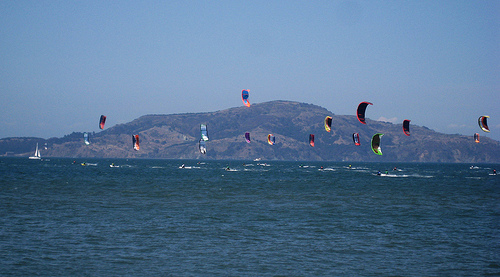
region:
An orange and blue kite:
[126, 128, 156, 170]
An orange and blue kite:
[232, 84, 255, 106]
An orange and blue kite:
[92, 110, 113, 129]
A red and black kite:
[354, 93, 379, 125]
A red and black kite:
[395, 114, 416, 139]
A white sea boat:
[20, 137, 52, 162]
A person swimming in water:
[373, 166, 386, 178]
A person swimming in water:
[222, 164, 239, 174]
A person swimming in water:
[388, 162, 410, 182]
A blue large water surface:
[163, 214, 372, 270]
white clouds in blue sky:
[0, 4, 57, 63]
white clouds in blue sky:
[47, 21, 92, 62]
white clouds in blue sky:
[126, 13, 157, 53]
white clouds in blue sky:
[186, 27, 228, 64]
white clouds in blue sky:
[274, 26, 309, 67]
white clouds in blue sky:
[354, 17, 407, 84]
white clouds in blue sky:
[386, 32, 443, 97]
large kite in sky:
[225, 78, 268, 113]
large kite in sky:
[125, 127, 145, 149]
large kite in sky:
[391, 104, 423, 158]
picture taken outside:
[5, 8, 496, 271]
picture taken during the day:
[15, 10, 499, 267]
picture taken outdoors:
[17, 13, 498, 273]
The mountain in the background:
[19, 60, 499, 251]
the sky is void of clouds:
[22, 15, 473, 85]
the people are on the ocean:
[12, 52, 499, 192]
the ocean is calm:
[35, 186, 413, 267]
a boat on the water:
[20, 122, 62, 193]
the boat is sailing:
[20, 129, 62, 190]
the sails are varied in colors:
[73, 66, 467, 181]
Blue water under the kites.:
[1, 155, 499, 275]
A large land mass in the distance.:
[1, 98, 499, 164]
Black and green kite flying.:
[367, 130, 385, 155]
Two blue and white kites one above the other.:
[195, 121, 210, 154]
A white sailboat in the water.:
[28, 138, 41, 160]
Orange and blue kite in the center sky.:
[241, 87, 252, 107]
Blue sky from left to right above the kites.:
[1, 1, 499, 86]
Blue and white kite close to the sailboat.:
[81, 130, 91, 146]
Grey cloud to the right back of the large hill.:
[378, 113, 397, 125]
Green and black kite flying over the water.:
[369, 130, 384, 155]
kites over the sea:
[50, 77, 497, 163]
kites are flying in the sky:
[40, 81, 495, 157]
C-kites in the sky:
[55, 60, 497, 170]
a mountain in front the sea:
[6, 88, 498, 184]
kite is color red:
[352, 93, 374, 128]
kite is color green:
[367, 127, 388, 161]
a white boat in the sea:
[24, 137, 48, 167]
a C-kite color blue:
[196, 116, 215, 141]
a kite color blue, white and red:
[126, 127, 145, 159]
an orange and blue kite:
[237, 83, 255, 117]